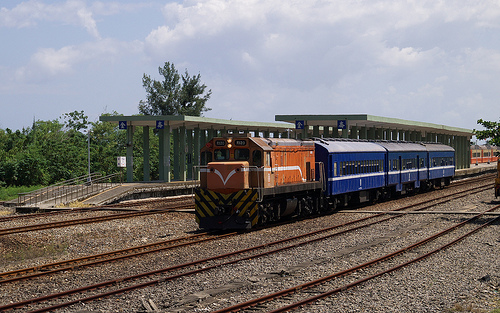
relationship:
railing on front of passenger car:
[241, 162, 264, 211] [192, 134, 458, 232]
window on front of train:
[323, 161, 362, 206] [143, 90, 478, 235]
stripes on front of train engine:
[186, 182, 263, 234] [187, 125, 459, 240]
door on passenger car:
[395, 152, 404, 189] [192, 134, 458, 232]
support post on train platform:
[155, 123, 182, 189] [31, 110, 475, 240]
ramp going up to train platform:
[36, 150, 146, 206] [122, 116, 496, 199]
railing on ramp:
[27, 167, 122, 209] [16, 172, 155, 209]